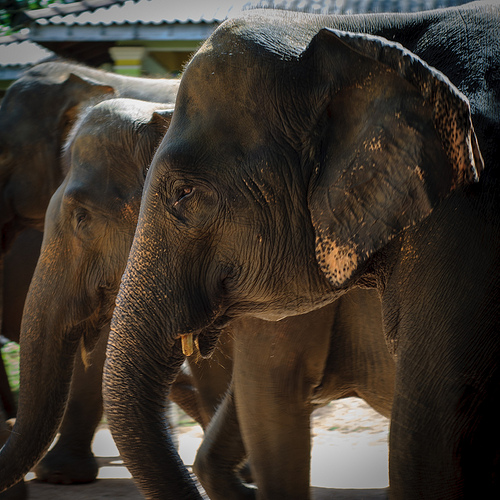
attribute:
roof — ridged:
[41, 7, 257, 50]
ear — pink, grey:
[301, 40, 480, 290]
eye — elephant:
[171, 181, 196, 203]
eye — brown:
[175, 181, 198, 200]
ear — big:
[287, 15, 492, 297]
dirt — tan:
[310, 396, 389, 496]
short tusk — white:
[165, 326, 210, 365]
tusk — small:
[178, 333, 194, 359]